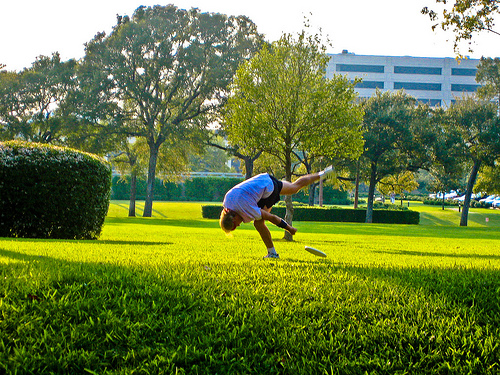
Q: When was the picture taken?
A: Daytime.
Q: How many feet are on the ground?
A: One.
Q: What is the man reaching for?
A: Frisbee.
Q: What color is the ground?
A: Green.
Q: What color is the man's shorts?
A: Black.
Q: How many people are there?
A: One.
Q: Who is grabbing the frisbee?
A: The man.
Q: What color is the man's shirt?
A: Gray.